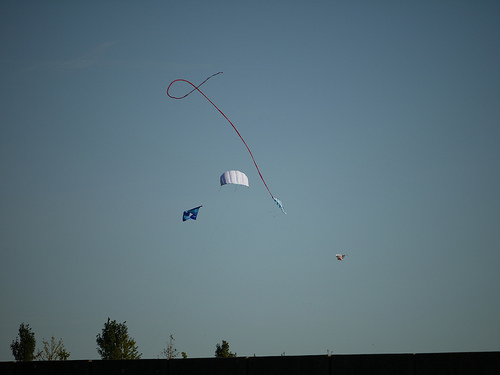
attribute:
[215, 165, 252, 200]
para sail — white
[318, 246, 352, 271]
kite — small, red, white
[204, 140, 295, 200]
para sail — white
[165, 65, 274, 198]
red tail — long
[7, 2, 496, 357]
sky — blue , light blue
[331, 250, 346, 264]
colorful kite — small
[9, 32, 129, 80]
cloud — white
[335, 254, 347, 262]
kite — small, yellow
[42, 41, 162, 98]
clouds — white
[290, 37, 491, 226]
clouds sky — white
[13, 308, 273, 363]
trees — leafy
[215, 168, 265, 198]
kites — flying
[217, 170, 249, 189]
kite — blue, white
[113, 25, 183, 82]
sky — blue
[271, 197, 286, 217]
kite — long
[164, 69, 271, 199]
tail — red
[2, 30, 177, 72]
cloud — white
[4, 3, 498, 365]
clouds — white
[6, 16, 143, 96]
clouds — white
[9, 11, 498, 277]
sky — light blue